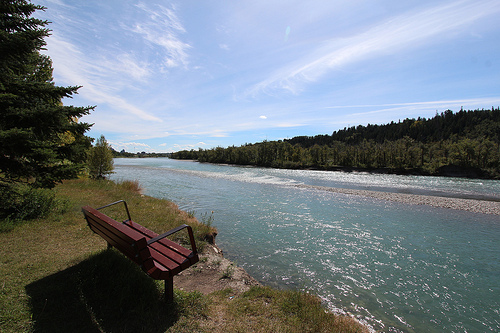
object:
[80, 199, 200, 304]
bench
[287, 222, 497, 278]
water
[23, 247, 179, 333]
shadow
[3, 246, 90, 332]
ground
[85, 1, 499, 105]
sky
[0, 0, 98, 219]
tree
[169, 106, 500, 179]
hill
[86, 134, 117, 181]
shrub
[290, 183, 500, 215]
sandbar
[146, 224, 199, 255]
arms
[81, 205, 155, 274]
back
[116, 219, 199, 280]
seat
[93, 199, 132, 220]
rail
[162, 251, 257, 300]
patch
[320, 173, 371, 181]
ripples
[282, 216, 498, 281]
river